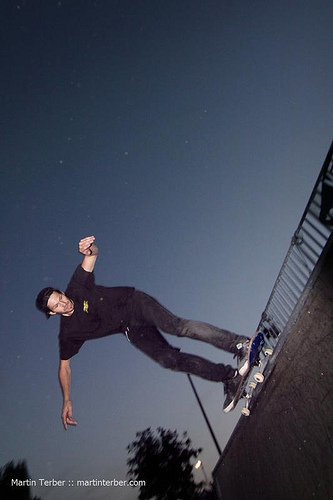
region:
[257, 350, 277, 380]
white wheels on a skateboard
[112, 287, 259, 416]
man wearing black jeans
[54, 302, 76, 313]
man with a beard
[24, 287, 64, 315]
man wearing a black hat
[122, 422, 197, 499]
Leaves on a tree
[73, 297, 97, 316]
logo on a tree shirt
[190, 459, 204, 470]
light on a pole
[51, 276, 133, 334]
man wearing a black tee shirt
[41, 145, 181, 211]
Star glaring in the night sky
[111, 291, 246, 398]
man wearing black pants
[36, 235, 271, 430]
man riding skateboard on ramp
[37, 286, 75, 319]
man wearing black hat backwards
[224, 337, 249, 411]
man wearing grey shoes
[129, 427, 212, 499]
black tree in background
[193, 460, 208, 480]
lightpost with light on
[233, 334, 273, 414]
skateboard with blue deck and white wheels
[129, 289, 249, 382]
man wearing dark jeans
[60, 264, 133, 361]
man wearing black shirt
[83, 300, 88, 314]
yellow mark on black shirt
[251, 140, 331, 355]
metal fence at top of ramp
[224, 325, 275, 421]
Man on a board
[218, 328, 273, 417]
Man is on a board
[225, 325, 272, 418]
Man on a skateboard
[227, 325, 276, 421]
Man is on a skateboard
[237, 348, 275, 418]
Skateboard has white wheels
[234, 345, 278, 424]
Skateboard has four wheels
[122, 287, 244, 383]
Man wearing pants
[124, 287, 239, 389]
Man is wearing pants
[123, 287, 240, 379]
Man wearing black pants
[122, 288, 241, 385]
Man is wearing black pants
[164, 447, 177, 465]
par tof a tree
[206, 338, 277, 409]
Man doing a trick on a skateboard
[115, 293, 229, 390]
man wearing black jeans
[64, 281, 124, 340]
man wearing a black tee shirt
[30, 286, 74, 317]
man wearing a black hat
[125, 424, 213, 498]
tree with leaves on it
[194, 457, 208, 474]
light on the pole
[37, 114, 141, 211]
clear sky with the stars glaring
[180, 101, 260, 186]
clear sky with the stars glaring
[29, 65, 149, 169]
clear sky with the stars glaring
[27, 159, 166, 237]
clear sky with the stars glaring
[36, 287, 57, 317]
a black baseball cap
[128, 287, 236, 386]
a man's black jean pants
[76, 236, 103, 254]
the hand of a man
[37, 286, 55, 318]
the hat is black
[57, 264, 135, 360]
the shirt is black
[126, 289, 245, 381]
the pants are black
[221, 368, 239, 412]
the shoe is black and white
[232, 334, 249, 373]
the shoe is black and white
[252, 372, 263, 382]
the wheel is white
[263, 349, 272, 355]
the wheel is white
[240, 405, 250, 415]
the wheel is white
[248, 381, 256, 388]
the wheel is white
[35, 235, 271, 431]
the man is on the skateboard